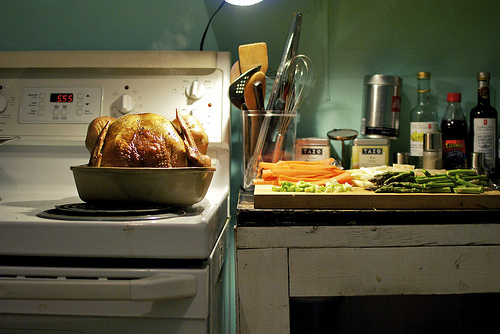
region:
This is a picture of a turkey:
[69, 115, 196, 189]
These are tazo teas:
[288, 115, 355, 157]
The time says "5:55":
[41, 75, 98, 121]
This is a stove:
[30, 66, 169, 301]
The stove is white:
[6, 97, 233, 330]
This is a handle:
[57, 263, 143, 311]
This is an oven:
[53, 265, 175, 321]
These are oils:
[412, 59, 495, 196]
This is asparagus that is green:
[380, 123, 476, 226]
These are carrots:
[261, 155, 308, 187]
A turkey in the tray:
[71, 104, 211, 208]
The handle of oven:
[0, 259, 200, 307]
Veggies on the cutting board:
[256, 161, 496, 206]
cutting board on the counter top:
[249, 193, 499, 208]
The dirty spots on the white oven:
[7, 223, 200, 330]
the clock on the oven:
[49, 88, 75, 106]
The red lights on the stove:
[48, 92, 76, 105]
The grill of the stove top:
[35, 202, 190, 220]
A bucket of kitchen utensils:
[228, 6, 307, 188]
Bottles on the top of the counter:
[412, 63, 497, 174]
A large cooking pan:
[68, 160, 215, 207]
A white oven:
[1, 52, 228, 332]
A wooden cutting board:
[251, 170, 498, 206]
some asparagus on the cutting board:
[366, 169, 486, 194]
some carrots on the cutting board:
[256, 159, 353, 187]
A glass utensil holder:
[240, 106, 297, 190]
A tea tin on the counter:
[350, 137, 390, 167]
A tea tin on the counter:
[293, 135, 330, 162]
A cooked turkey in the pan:
[86, 106, 209, 165]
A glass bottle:
[406, 70, 438, 163]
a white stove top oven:
[1, 48, 232, 333]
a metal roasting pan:
[66, 163, 214, 205]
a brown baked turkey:
[86, 107, 211, 166]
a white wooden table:
[238, 183, 498, 330]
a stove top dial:
[184, 77, 205, 99]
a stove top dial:
[115, 91, 134, 113]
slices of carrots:
[253, 162, 348, 184]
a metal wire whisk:
[266, 55, 313, 162]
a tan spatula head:
[237, 42, 267, 76]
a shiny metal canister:
[361, 73, 400, 132]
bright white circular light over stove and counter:
[216, 0, 266, 10]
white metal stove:
[1, 45, 238, 332]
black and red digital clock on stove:
[46, 90, 76, 105]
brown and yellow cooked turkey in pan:
[67, 103, 219, 207]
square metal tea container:
[337, 130, 392, 181]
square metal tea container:
[291, 134, 336, 180]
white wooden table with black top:
[232, 156, 498, 332]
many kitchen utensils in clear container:
[222, 6, 319, 194]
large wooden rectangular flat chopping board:
[250, 161, 498, 213]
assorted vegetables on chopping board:
[249, 157, 497, 193]